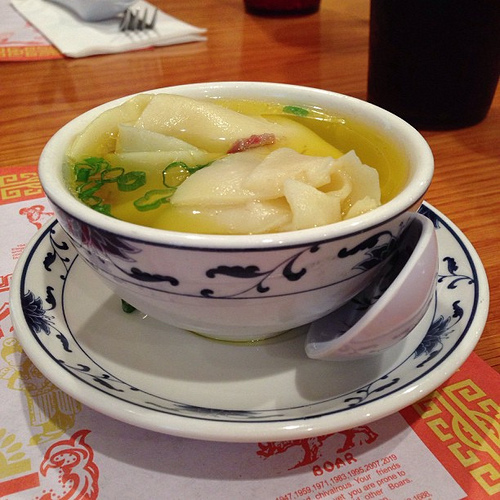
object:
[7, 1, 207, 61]
napkin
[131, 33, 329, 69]
table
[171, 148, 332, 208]
wontons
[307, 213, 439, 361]
soup spoon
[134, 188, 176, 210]
green onions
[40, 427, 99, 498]
red design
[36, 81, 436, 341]
bowl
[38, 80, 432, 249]
soup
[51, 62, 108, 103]
table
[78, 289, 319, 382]
shadow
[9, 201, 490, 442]
plate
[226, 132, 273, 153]
meat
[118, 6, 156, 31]
fork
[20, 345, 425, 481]
shadow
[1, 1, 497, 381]
table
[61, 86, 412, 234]
food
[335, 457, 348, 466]
words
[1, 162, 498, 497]
place mat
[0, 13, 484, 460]
scene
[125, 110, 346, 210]
soup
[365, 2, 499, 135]
glass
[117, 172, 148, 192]
onions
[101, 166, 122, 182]
scallions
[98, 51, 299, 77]
table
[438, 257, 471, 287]
design